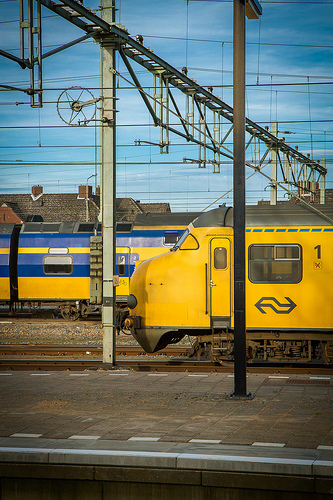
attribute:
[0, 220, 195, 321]
train — yellow, blue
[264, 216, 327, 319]
train — yellow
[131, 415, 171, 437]
floor — tiled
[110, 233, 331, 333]
train — yellow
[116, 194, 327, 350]
train — blue, yellow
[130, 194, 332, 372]
train — yellow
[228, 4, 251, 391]
pole — metallic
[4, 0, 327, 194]
sky — blue